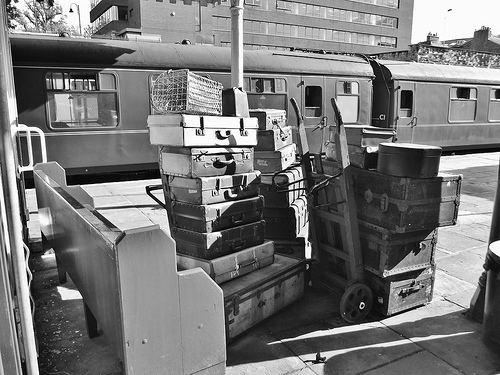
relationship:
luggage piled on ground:
[145, 111, 259, 148] [14, 148, 498, 374]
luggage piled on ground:
[157, 143, 258, 179] [14, 148, 498, 374]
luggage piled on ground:
[158, 168, 263, 205] [14, 148, 498, 374]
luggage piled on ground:
[164, 193, 267, 234] [14, 148, 498, 374]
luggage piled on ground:
[174, 238, 276, 284] [14, 148, 498, 374]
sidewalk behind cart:
[18, 147, 498, 370] [262, 89, 469, 331]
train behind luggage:
[56, 17, 485, 168] [164, 108, 266, 253]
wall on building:
[396, 7, 418, 54] [82, 7, 480, 37]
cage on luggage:
[150, 71, 234, 111] [135, 119, 321, 340]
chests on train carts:
[352, 144, 467, 319] [268, 96, 378, 326]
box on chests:
[372, 107, 450, 214] [359, 158, 464, 241]